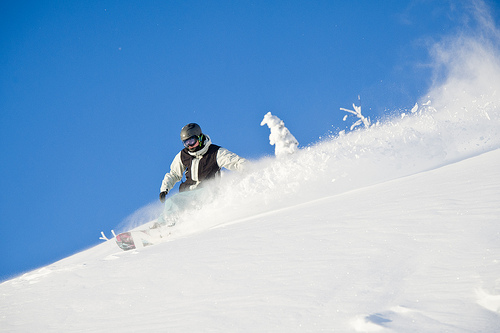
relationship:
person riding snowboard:
[157, 120, 248, 223] [120, 213, 266, 250]